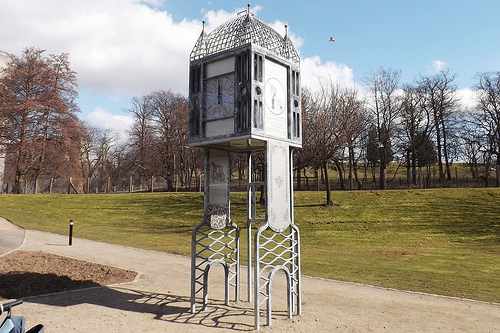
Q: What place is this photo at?
A: It is at the park.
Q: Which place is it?
A: It is a park.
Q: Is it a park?
A: Yes, it is a park.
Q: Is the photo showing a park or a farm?
A: It is showing a park.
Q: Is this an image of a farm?
A: No, the picture is showing a park.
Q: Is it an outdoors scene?
A: Yes, it is outdoors.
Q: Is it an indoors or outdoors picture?
A: It is outdoors.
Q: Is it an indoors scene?
A: No, it is outdoors.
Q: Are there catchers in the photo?
A: No, there are no catchers.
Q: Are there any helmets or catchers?
A: No, there are no catchers or helmets.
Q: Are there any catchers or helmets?
A: No, there are no catchers or helmets.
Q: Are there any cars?
A: No, there are no cars.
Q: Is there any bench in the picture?
A: No, there are no benches.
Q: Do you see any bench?
A: No, there are no benches.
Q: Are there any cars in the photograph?
A: No, there are no cars.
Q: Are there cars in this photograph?
A: No, there are no cars.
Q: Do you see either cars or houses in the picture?
A: No, there are no cars or houses.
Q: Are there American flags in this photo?
A: No, there are no American flags.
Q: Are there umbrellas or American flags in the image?
A: No, there are no American flags or umbrellas.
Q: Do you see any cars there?
A: No, there are no cars.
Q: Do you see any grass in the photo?
A: Yes, there is grass.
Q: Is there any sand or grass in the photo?
A: Yes, there is grass.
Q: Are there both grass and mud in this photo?
A: No, there is grass but no mud.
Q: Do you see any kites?
A: No, there are no kites.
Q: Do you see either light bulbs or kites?
A: No, there are no kites or light bulbs.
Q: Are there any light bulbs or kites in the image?
A: No, there are no kites or light bulbs.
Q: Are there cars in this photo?
A: No, there are no cars.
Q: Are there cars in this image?
A: No, there are no cars.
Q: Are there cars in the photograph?
A: No, there are no cars.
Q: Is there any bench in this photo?
A: No, there are no benches.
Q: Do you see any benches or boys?
A: No, there are no benches or boys.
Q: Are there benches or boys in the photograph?
A: No, there are no benches or boys.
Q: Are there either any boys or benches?
A: No, there are no benches or boys.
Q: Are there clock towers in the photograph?
A: Yes, there is a clock tower.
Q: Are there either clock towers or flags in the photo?
A: Yes, there is a clock tower.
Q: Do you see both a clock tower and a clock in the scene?
A: Yes, there are both a clock tower and a clock.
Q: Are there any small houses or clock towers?
A: Yes, there is a small clock tower.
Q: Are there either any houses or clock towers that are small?
A: Yes, the clock tower is small.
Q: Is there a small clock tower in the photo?
A: Yes, there is a small clock tower.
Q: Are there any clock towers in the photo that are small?
A: Yes, there is a clock tower that is small.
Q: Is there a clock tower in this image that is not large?
A: Yes, there is a small clock tower.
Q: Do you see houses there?
A: No, there are no houses.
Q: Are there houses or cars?
A: No, there are no houses or cars.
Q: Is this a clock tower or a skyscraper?
A: This is a clock tower.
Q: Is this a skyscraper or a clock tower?
A: This is a clock tower.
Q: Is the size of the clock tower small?
A: Yes, the clock tower is small.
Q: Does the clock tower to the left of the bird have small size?
A: Yes, the clock tower is small.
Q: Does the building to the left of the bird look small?
A: Yes, the clock tower is small.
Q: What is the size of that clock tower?
A: The clock tower is small.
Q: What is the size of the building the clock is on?
A: The clock tower is small.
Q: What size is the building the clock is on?
A: The clock tower is small.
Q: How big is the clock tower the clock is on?
A: The clock tower is small.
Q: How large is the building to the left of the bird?
A: The clock tower is small.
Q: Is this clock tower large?
A: No, the clock tower is small.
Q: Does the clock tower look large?
A: No, the clock tower is small.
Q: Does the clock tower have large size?
A: No, the clock tower is small.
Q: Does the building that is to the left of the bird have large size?
A: No, the clock tower is small.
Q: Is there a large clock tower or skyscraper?
A: No, there is a clock tower but it is small.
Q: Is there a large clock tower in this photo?
A: No, there is a clock tower but it is small.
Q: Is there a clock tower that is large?
A: No, there is a clock tower but it is small.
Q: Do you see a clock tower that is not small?
A: No, there is a clock tower but it is small.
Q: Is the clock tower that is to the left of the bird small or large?
A: The clock tower is small.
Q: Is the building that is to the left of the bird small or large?
A: The clock tower is small.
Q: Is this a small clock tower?
A: Yes, this is a small clock tower.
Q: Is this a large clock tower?
A: No, this is a small clock tower.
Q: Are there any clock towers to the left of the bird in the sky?
A: Yes, there is a clock tower to the left of the bird.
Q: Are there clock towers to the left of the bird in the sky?
A: Yes, there is a clock tower to the left of the bird.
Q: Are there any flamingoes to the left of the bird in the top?
A: No, there is a clock tower to the left of the bird.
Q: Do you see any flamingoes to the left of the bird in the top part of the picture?
A: No, there is a clock tower to the left of the bird.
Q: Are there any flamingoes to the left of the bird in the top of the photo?
A: No, there is a clock tower to the left of the bird.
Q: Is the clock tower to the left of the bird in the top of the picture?
A: Yes, the clock tower is to the left of the bird.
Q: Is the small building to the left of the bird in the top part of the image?
A: Yes, the clock tower is to the left of the bird.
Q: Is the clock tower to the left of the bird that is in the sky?
A: Yes, the clock tower is to the left of the bird.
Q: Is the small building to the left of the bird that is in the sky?
A: Yes, the clock tower is to the left of the bird.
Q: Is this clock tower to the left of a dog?
A: No, the clock tower is to the left of the bird.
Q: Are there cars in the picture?
A: No, there are no cars.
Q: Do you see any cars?
A: No, there are no cars.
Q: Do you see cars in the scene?
A: No, there are no cars.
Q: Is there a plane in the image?
A: No, there are no airplanes.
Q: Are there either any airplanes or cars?
A: No, there are no airplanes or cars.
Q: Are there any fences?
A: Yes, there is a fence.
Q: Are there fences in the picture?
A: Yes, there is a fence.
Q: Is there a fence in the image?
A: Yes, there is a fence.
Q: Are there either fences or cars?
A: Yes, there is a fence.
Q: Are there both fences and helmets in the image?
A: No, there is a fence but no helmets.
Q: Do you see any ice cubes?
A: No, there are no ice cubes.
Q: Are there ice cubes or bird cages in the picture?
A: No, there are no ice cubes or bird cages.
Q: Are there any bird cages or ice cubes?
A: No, there are no ice cubes or bird cages.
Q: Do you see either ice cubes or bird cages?
A: No, there are no ice cubes or bird cages.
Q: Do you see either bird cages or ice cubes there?
A: No, there are no ice cubes or bird cages.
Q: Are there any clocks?
A: Yes, there is a clock.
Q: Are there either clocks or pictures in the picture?
A: Yes, there is a clock.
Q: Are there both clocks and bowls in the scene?
A: No, there is a clock but no bowls.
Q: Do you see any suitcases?
A: No, there are no suitcases.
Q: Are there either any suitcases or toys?
A: No, there are no suitcases or toys.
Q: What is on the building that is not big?
A: The clock is on the clock tower.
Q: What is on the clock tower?
A: The clock is on the clock tower.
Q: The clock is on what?
A: The clock is on the clock tower.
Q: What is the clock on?
A: The clock is on the clock tower.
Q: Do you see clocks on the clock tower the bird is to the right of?
A: Yes, there is a clock on the clock tower.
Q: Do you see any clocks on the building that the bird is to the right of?
A: Yes, there is a clock on the clock tower.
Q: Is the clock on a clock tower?
A: Yes, the clock is on a clock tower.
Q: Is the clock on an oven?
A: No, the clock is on a clock tower.